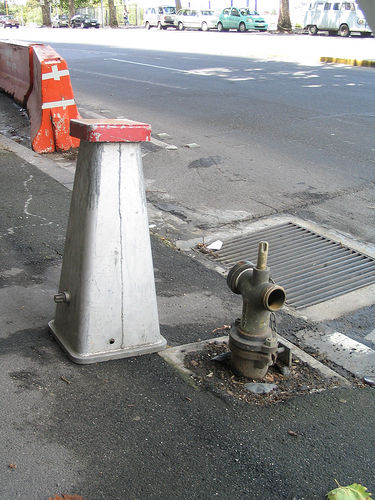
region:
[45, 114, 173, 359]
silver cone with red top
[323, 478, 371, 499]
dead leaf on ground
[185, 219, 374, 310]
grey metal storm grate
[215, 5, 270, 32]
small light green car parked on road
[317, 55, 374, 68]
yellow stripe on curb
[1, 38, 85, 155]
orange and white concrete barriers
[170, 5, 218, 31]
white sport utility vehicle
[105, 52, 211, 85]
white stripe painted on road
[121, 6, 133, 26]
person walking on sidewalk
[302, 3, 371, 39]
white Volkswagon bus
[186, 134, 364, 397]
water hydrant near road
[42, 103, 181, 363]
red top on white object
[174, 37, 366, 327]
drain grate in road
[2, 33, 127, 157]
orange and white barrier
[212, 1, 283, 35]
green car parked at curb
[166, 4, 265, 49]
white station wagon parked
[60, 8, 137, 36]
black car parked at curb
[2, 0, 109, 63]
red car driving in street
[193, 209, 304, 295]
white paper on grate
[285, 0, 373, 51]
white Volkswagon van parked at curb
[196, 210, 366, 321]
Sewer grate in the street.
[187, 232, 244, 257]
Garbage on top of the grate.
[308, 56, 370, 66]
Yellow curb on the sidewalk.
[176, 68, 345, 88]
Shadows on the street from the sun.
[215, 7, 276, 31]
A small mint green car that is parked.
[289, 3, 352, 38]
Volkswagon van that is parked.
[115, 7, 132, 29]
Person walking on the sidewalk.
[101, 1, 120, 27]
Large tree trunk on the sidewalk.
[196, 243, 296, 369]
A place to hook up a fire hose.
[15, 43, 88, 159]
Orange and white safety barriers.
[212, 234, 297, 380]
The water hydrant next to the road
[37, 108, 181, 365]
THe grey and red cover of the hydrant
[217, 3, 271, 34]
The seafoam green car across the street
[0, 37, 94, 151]
The orange barricade behind the hydrant cover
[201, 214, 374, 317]
The grate in the street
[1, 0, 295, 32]
The trees shown across the street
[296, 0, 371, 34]
The light blue VW bus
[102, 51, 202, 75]
The white line in the street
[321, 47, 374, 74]
The yellow curc in the street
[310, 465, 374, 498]
The leaf on the ground near the hyrdrant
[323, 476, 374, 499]
Green leaf on the ground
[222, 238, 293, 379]
Rusted metal hose attachment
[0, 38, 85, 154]
Orange construction barrier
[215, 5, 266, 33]
Mint green compact car parked on the side of a road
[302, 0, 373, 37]
Old style white van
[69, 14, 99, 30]
Black sedan parked on the side of the road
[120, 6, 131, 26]
Person on a sidewalk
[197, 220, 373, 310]
Metal drainage grate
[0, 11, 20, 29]
Burgundy car driving on the road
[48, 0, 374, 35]
Six vehicles parked on the side of a road